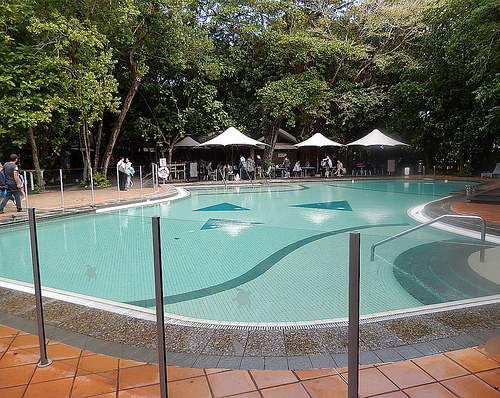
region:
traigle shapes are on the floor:
[201, 197, 266, 238]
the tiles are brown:
[213, 360, 313, 392]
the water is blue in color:
[191, 183, 316, 233]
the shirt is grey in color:
[4, 160, 20, 188]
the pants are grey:
[1, 188, 31, 210]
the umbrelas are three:
[197, 120, 422, 157]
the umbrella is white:
[215, 118, 257, 143]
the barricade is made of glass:
[85, 240, 472, 385]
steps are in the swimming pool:
[392, 240, 476, 291]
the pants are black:
[116, 173, 126, 185]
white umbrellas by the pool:
[170, 123, 415, 156]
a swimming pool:
[26, 178, 495, 335]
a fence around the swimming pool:
[7, 194, 457, 396]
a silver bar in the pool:
[365, 193, 490, 257]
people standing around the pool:
[8, 139, 408, 204]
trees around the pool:
[5, 25, 497, 130]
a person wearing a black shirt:
[3, 156, 23, 210]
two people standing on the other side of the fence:
[113, 156, 138, 185]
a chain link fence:
[14, 154, 173, 199]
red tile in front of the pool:
[1, 333, 498, 391]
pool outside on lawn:
[1, 180, 468, 299]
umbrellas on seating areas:
[169, 125, 416, 179]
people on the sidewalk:
[4, 145, 145, 191]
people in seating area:
[181, 149, 341, 174]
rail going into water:
[363, 215, 493, 249]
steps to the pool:
[393, 243, 483, 296]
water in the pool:
[32, 224, 377, 300]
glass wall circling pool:
[1, 198, 489, 383]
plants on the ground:
[78, 165, 111, 187]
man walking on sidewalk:
[0, 155, 30, 210]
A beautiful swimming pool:
[101, 200, 451, 305]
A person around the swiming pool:
[0, 147, 31, 217]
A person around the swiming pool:
[107, 153, 137, 181]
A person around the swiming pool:
[312, 154, 342, 184]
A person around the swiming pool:
[332, 158, 343, 178]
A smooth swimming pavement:
[18, 334, 152, 395]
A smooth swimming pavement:
[180, 318, 265, 395]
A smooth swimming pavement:
[375, 364, 460, 396]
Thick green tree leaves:
[251, 20, 338, 138]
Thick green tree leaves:
[421, 5, 498, 136]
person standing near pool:
[110, 154, 140, 192]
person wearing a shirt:
[1, 144, 26, 212]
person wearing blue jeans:
[4, 152, 21, 221]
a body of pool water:
[175, 229, 363, 280]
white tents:
[174, 111, 416, 158]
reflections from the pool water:
[193, 214, 399, 246]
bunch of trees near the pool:
[15, 7, 485, 173]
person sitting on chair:
[197, 153, 235, 188]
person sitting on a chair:
[311, 150, 348, 175]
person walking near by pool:
[0, 148, 30, 215]